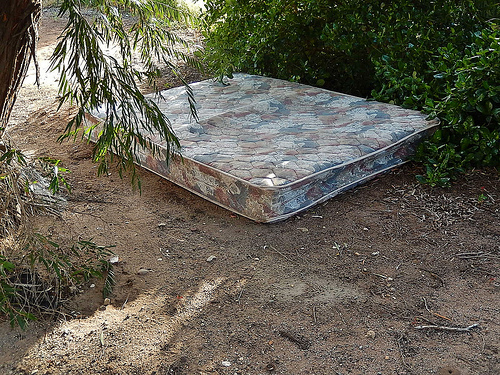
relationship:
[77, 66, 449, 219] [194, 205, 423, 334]
matress on dirt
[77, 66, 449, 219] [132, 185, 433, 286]
matress on dirt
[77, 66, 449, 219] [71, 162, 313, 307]
matress on ground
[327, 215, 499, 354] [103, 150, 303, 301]
dirt on ground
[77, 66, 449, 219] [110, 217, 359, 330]
matress on ground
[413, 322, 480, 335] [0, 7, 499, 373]
stick on ground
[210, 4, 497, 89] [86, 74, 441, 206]
tree next to mattress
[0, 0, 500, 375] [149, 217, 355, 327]
dirt on ground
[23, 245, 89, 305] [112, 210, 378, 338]
branches on ground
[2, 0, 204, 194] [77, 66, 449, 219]
tree near matress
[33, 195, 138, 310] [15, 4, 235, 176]
roots of tree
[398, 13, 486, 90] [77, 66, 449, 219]
plants near matress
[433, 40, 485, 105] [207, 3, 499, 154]
leaves of plants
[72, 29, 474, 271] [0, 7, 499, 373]
matress on ground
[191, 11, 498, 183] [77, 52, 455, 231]
bush behind mattress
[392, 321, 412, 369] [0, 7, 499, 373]
stick on ground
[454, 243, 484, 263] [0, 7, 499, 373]
stick on ground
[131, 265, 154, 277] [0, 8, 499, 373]
rock in sand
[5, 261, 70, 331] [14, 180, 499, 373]
hole in dirt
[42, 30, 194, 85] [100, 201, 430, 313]
sunlight on ground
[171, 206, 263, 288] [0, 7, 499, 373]
rocks on ground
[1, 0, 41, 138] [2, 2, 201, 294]
trunk on tree